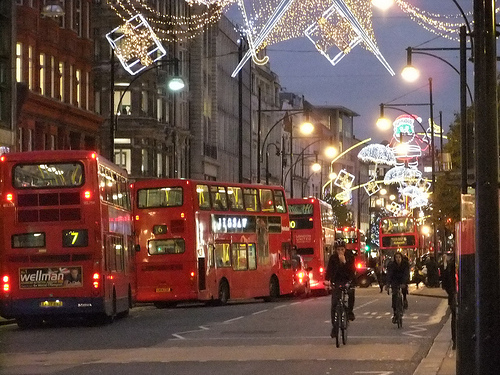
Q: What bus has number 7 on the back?
A: Front bus.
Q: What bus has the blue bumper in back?
A: Front bus.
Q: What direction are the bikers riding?
A: Towards the camera.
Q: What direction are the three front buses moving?
A: Away from camera.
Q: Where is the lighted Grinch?
A: Middle right background.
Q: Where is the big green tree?
A: Right of background light decorations.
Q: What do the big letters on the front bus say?
A: Wellman.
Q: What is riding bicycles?
A: The people.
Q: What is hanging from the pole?
A: The lights.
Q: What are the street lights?
A: On.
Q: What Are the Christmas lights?
A: Lit up.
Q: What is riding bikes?
A: Two people.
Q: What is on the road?
A: The white lines.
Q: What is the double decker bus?
A: The back of the red.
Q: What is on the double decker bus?
A: The lights are.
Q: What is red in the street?
A: Buses.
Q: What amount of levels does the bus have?
A: Two.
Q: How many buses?
A: Four.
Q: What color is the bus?
A: Red.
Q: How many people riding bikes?
A: Two.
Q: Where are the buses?
A: Left side of road.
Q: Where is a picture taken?
A: In the city.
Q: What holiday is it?
A: Christmas.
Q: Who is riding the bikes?
A: Two men.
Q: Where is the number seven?
A: The first bus.